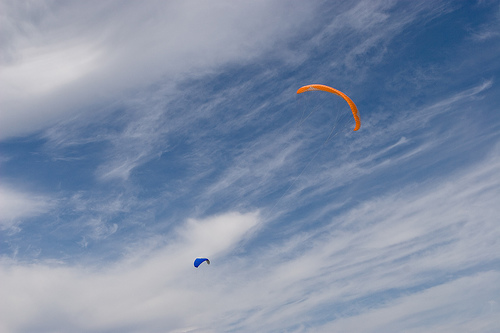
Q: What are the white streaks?
A: Clouds.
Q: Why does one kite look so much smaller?
A: Distance.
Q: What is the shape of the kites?
A: Half oval.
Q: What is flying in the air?
A: Kites.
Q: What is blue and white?
A: Sky.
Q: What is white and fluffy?
A: Clouds.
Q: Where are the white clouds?
A: The sky.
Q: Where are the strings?
A: Attached to the kites.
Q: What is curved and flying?
A: Kites.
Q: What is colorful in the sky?
A: Kites.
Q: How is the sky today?
A: Cloudy.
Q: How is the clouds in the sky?
A: White.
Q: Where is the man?
A: In air.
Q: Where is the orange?
A: The sky.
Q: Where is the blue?
A: In sky.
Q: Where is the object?
A: The air.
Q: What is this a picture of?
A: Parachutes.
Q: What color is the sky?
A: Blue.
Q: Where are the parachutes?
A: Sky.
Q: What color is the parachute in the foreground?
A: Orange.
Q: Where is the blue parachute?
A: Background.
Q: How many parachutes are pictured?
A: 2.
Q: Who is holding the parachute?
A: Nobody.